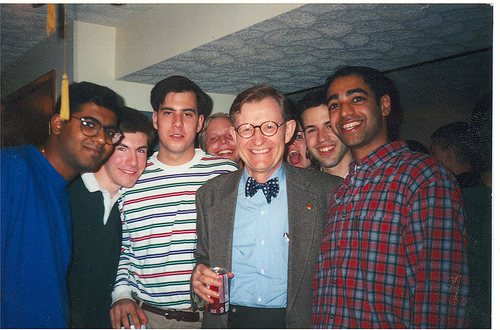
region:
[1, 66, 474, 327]
group of smiling people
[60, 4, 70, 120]
hanging gold tassel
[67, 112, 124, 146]
dark rimmed eye glasses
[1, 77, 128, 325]
man wearing a blue shirt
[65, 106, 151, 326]
man wearing black shirt with white collar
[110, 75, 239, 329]
man wearing striped shirt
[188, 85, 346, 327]
man wearing suit and bow tie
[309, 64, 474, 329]
man wearing plaid shirt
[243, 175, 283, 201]
black and white bow tie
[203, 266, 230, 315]
open soft drink can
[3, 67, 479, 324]
Group of young men taking a picture with an older gentleman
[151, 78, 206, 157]
The only person not smiling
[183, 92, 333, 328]
Man holding a soda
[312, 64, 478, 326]
Guy in red and blue plaid shirt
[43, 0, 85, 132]
Graduation tassel hanging from the ceiling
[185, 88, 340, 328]
Man wearing a blue bow tie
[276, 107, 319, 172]
Excited person peeking from the back of the group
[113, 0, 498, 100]
Blue wall paper on the ceiling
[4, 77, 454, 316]
Group of smiling colleagues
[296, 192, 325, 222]
Red pin in the lapel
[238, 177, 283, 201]
A plaid bow tie.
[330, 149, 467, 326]
A red, blue and gray plaid shirt.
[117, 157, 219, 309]
Red, blue, green and white long sleeve shirt.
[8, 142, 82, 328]
Plain blue tee shirt.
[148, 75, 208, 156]
Not some happy guy.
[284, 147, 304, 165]
A mouth that is open.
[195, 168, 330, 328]
A gray blazer.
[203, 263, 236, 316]
A hand holding a Dr. Pepper can.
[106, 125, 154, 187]
Wonderful pink cheeks on a smiling face.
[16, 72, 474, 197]
The whole group is having a meet up.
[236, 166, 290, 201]
blue and white tie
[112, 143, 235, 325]
person wearing striped sweater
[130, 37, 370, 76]
the ceiling is white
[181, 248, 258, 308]
holding a pop can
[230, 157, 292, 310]
blue shirt with buttons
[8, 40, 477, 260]
group of people together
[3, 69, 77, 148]
the door is brown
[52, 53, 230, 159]
people with black hair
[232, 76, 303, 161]
person with brown hair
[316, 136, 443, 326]
red and blue plaid shirt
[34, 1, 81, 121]
gold tassel hanging from ceiling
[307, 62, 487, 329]
guy wearing red and blue shirt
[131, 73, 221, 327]
guy wearing striped shirt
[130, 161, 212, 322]
white shirt with green, red, and blue stripes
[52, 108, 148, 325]
guy wearing dark sweater with white shirt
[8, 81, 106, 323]
guy wearing blue shirt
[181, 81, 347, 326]
man holding can in hand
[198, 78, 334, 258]
guy wearing blue shirt and bowtie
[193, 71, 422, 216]
people in group smiling